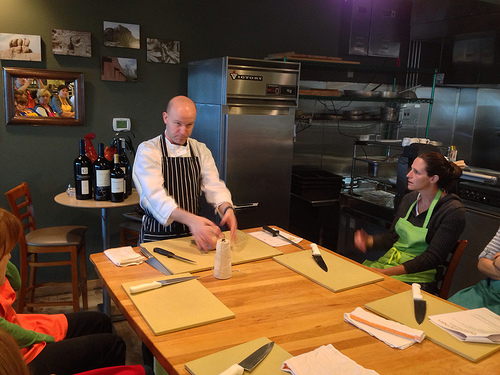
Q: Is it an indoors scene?
A: Yes, it is indoors.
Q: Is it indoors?
A: Yes, it is indoors.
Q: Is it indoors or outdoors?
A: It is indoors.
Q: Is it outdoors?
A: No, it is indoors.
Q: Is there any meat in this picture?
A: Yes, there is meat.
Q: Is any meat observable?
A: Yes, there is meat.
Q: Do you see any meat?
A: Yes, there is meat.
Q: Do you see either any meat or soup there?
A: Yes, there is meat.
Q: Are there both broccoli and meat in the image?
A: No, there is meat but no broccoli.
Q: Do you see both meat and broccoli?
A: No, there is meat but no broccoli.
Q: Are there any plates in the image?
A: No, there are no plates.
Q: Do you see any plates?
A: No, there are no plates.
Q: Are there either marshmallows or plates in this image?
A: No, there are no plates or marshmallows.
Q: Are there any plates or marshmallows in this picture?
A: No, there are no plates or marshmallows.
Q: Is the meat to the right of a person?
A: Yes, the meat is to the right of a person.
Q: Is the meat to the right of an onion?
A: No, the meat is to the right of a person.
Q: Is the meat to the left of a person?
A: No, the meat is to the right of a person.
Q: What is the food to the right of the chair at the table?
A: The food is meat.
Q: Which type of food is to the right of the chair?
A: The food is meat.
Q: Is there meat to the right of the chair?
A: Yes, there is meat to the right of the chair.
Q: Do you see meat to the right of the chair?
A: Yes, there is meat to the right of the chair.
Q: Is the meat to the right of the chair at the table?
A: Yes, the meat is to the right of the chair.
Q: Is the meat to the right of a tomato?
A: No, the meat is to the right of the chair.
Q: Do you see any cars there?
A: No, there are no cars.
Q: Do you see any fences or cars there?
A: No, there are no cars or fences.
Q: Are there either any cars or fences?
A: No, there are no cars or fences.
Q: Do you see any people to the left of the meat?
A: Yes, there is a person to the left of the meat.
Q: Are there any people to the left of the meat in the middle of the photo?
A: Yes, there is a person to the left of the meat.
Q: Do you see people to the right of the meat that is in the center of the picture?
A: No, the person is to the left of the meat.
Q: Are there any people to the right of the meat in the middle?
A: No, the person is to the left of the meat.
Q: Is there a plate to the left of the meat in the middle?
A: No, there is a person to the left of the meat.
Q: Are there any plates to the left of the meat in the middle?
A: No, there is a person to the left of the meat.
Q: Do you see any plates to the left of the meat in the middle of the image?
A: No, there is a person to the left of the meat.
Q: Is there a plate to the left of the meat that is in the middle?
A: No, there is a person to the left of the meat.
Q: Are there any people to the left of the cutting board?
A: Yes, there is a person to the left of the cutting board.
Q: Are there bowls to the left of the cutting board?
A: No, there is a person to the left of the cutting board.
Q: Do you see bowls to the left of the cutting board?
A: No, there is a person to the left of the cutting board.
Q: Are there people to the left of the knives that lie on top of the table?
A: Yes, there is a person to the left of the knives.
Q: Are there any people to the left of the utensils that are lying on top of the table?
A: Yes, there is a person to the left of the knives.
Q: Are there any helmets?
A: No, there are no helmets.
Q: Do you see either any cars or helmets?
A: No, there are no helmets or cars.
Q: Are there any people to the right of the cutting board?
A: Yes, there is a person to the right of the cutting board.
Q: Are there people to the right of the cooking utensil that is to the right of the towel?
A: Yes, there is a person to the right of the cutting board.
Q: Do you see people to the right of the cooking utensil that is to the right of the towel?
A: Yes, there is a person to the right of the cutting board.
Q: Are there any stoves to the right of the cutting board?
A: No, there is a person to the right of the cutting board.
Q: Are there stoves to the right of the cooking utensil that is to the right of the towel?
A: No, there is a person to the right of the cutting board.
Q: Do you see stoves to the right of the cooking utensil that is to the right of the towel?
A: No, there is a person to the right of the cutting board.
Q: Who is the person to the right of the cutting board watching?
A: The person is watching the man.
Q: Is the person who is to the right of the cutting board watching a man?
A: Yes, the person is watching a man.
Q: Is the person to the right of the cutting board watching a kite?
A: No, the person is watching a man.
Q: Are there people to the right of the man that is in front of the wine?
A: Yes, there is a person to the right of the man.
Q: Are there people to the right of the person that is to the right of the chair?
A: Yes, there is a person to the right of the man.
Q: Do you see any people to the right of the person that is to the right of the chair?
A: Yes, there is a person to the right of the man.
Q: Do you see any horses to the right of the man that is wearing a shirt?
A: No, there is a person to the right of the man.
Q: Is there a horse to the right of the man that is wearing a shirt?
A: No, there is a person to the right of the man.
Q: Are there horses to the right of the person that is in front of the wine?
A: No, there is a person to the right of the man.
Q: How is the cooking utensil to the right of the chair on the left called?
A: The cooking utensil is a cutting board.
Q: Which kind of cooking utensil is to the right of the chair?
A: The cooking utensil is a cutting board.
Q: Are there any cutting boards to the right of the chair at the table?
A: Yes, there is a cutting board to the right of the chair.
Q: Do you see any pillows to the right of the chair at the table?
A: No, there is a cutting board to the right of the chair.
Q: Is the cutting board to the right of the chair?
A: Yes, the cutting board is to the right of the chair.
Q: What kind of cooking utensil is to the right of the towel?
A: The cooking utensil is a cutting board.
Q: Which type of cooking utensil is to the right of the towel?
A: The cooking utensil is a cutting board.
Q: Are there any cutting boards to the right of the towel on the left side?
A: Yes, there is a cutting board to the right of the towel.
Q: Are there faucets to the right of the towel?
A: No, there is a cutting board to the right of the towel.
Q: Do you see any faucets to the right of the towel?
A: No, there is a cutting board to the right of the towel.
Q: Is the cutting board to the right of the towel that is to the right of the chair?
A: Yes, the cutting board is to the right of the towel.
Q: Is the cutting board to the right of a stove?
A: No, the cutting board is to the right of the towel.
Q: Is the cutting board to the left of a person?
A: No, the cutting board is to the right of a person.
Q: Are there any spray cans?
A: No, there are no spray cans.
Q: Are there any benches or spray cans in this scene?
A: No, there are no spray cans or benches.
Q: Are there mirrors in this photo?
A: No, there are no mirrors.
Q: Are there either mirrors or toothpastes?
A: No, there are no mirrors or toothpastes.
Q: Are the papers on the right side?
A: Yes, the papers are on the right of the image.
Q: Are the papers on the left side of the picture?
A: No, the papers are on the right of the image.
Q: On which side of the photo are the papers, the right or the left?
A: The papers are on the right of the image.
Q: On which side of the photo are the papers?
A: The papers are on the right of the image.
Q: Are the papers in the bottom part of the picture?
A: Yes, the papers are in the bottom of the image.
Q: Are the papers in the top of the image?
A: No, the papers are in the bottom of the image.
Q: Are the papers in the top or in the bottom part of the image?
A: The papers are in the bottom of the image.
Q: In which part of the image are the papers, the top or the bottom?
A: The papers are in the bottom of the image.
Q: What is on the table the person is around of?
A: The papers are on the table.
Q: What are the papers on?
A: The papers are on the table.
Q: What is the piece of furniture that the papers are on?
A: The piece of furniture is a table.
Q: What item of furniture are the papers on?
A: The papers are on the table.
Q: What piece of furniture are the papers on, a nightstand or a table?
A: The papers are on a table.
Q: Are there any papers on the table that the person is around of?
A: Yes, there are papers on the table.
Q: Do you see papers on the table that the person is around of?
A: Yes, there are papers on the table.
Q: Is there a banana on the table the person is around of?
A: No, there are papers on the table.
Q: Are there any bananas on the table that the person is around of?
A: No, there are papers on the table.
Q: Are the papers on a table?
A: Yes, the papers are on a table.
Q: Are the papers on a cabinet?
A: No, the papers are on a table.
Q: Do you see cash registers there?
A: No, there are no cash registers.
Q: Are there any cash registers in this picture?
A: No, there are no cash registers.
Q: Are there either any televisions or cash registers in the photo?
A: No, there are no cash registers or televisions.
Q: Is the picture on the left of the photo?
A: Yes, the picture is on the left of the image.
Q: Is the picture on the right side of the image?
A: No, the picture is on the left of the image.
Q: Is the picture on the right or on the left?
A: The picture is on the left of the image.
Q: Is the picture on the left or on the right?
A: The picture is on the left of the image.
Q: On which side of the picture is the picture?
A: The picture is on the left of the image.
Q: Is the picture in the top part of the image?
A: Yes, the picture is in the top of the image.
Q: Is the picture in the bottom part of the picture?
A: No, the picture is in the top of the image.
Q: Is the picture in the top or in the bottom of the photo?
A: The picture is in the top of the image.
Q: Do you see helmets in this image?
A: No, there are no helmets.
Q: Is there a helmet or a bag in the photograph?
A: No, there are no helmets or bags.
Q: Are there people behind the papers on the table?
A: Yes, there is a person behind the papers.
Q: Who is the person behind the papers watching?
A: The person is watching the man.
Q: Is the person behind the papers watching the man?
A: Yes, the person is watching the man.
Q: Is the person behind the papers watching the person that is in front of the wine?
A: Yes, the person is watching the man.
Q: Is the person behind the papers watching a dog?
A: No, the person is watching the man.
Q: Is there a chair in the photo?
A: Yes, there is a chair.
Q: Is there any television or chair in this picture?
A: Yes, there is a chair.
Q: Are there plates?
A: No, there are no plates.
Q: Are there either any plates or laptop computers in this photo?
A: No, there are no plates or laptop computers.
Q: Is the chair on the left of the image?
A: Yes, the chair is on the left of the image.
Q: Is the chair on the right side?
A: No, the chair is on the left of the image.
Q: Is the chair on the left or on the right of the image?
A: The chair is on the left of the image.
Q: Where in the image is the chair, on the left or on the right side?
A: The chair is on the left of the image.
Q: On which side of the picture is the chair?
A: The chair is on the left of the image.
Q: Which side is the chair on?
A: The chair is on the left of the image.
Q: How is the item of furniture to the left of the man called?
A: The piece of furniture is a chair.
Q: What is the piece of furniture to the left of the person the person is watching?
A: The piece of furniture is a chair.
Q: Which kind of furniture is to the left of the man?
A: The piece of furniture is a chair.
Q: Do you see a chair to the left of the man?
A: Yes, there is a chair to the left of the man.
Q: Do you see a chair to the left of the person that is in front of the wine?
A: Yes, there is a chair to the left of the man.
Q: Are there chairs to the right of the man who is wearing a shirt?
A: No, the chair is to the left of the man.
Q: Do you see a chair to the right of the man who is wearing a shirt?
A: No, the chair is to the left of the man.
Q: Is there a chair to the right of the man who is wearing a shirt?
A: No, the chair is to the left of the man.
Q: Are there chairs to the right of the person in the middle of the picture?
A: No, the chair is to the left of the man.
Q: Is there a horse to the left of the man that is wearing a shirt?
A: No, there is a chair to the left of the man.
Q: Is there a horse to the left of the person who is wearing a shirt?
A: No, there is a chair to the left of the man.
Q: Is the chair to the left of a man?
A: Yes, the chair is to the left of a man.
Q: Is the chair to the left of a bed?
A: No, the chair is to the left of a man.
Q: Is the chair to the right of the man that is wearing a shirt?
A: No, the chair is to the left of the man.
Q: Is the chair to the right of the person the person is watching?
A: No, the chair is to the left of the man.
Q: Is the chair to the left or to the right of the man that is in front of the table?
A: The chair is to the left of the man.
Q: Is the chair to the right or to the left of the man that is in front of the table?
A: The chair is to the left of the man.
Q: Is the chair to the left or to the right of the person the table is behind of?
A: The chair is to the left of the man.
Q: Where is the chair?
A: The chair is at the table.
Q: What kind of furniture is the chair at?
A: The chair is at the table.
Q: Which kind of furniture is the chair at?
A: The chair is at the table.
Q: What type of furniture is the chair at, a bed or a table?
A: The chair is at a table.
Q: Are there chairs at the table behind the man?
A: Yes, there is a chair at the table.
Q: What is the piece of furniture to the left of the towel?
A: The piece of furniture is a chair.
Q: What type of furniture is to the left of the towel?
A: The piece of furniture is a chair.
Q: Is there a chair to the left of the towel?
A: Yes, there is a chair to the left of the towel.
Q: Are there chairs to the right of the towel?
A: No, the chair is to the left of the towel.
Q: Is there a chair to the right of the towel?
A: No, the chair is to the left of the towel.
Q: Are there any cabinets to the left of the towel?
A: No, there is a chair to the left of the towel.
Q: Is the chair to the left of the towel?
A: Yes, the chair is to the left of the towel.